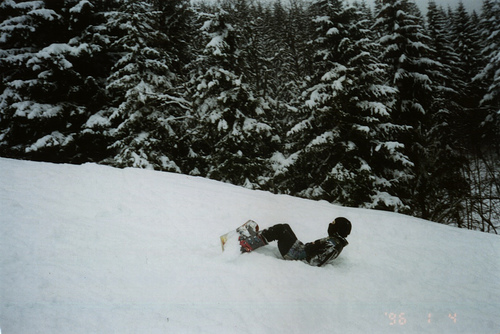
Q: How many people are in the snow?
A: One.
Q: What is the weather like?
A: Cloudy.